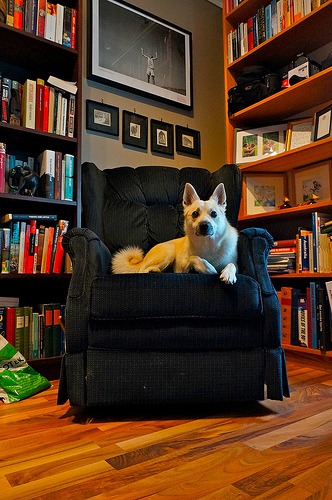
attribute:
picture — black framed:
[176, 122, 200, 153]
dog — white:
[110, 178, 238, 285]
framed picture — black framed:
[121, 109, 147, 152]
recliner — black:
[28, 138, 303, 324]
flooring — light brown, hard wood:
[213, 444, 272, 474]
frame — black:
[84, 98, 120, 139]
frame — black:
[121, 110, 149, 151]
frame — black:
[150, 117, 175, 158]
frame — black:
[175, 122, 202, 160]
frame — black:
[87, 1, 195, 116]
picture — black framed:
[83, 0, 192, 112]